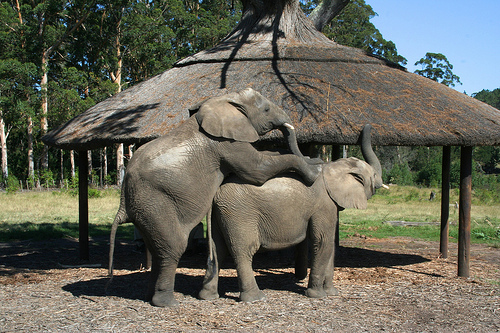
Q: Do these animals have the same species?
A: Yes, all the animals are elephants.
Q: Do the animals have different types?
A: No, all the animals are elephants.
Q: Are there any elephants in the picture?
A: Yes, there is an elephant.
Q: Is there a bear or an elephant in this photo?
A: Yes, there is an elephant.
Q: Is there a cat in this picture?
A: No, there are no cats.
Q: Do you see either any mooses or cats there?
A: No, there are no cats or mooses.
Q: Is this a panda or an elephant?
A: This is an elephant.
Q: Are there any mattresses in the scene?
A: No, there are no mattresses.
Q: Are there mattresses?
A: No, there are no mattresses.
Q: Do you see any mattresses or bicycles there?
A: No, there are no mattresses or bicycles.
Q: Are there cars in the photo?
A: No, there are no cars.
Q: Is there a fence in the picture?
A: Yes, there is a fence.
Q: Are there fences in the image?
A: Yes, there is a fence.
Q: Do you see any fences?
A: Yes, there is a fence.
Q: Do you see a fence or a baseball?
A: Yes, there is a fence.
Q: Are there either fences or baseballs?
A: Yes, there is a fence.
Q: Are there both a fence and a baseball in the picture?
A: No, there is a fence but no baseballs.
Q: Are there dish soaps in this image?
A: No, there are no dish soaps.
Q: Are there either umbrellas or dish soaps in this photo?
A: No, there are no dish soaps or umbrellas.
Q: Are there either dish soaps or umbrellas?
A: No, there are no dish soaps or umbrellas.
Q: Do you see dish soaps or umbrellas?
A: No, there are no dish soaps or umbrellas.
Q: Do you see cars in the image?
A: No, there are no cars.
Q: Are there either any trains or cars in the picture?
A: No, there are no cars or trains.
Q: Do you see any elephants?
A: Yes, there is an elephant.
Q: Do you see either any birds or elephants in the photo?
A: Yes, there is an elephant.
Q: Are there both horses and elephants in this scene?
A: No, there is an elephant but no horses.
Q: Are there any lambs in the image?
A: No, there are no lambs.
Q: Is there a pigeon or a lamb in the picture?
A: No, there are no lambs or pigeons.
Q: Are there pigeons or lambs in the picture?
A: No, there are no lambs or pigeons.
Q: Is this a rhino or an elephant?
A: This is an elephant.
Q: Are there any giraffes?
A: No, there are no giraffes.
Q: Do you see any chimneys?
A: No, there are no chimneys.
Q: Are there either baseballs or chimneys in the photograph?
A: No, there are no chimneys or baseballs.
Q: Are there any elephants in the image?
A: Yes, there are elephants.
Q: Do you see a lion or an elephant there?
A: Yes, there are elephants.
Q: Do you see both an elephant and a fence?
A: Yes, there are both an elephant and a fence.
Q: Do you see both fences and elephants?
A: Yes, there are both elephants and a fence.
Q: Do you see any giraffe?
A: No, there are no giraffes.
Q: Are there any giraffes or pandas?
A: No, there are no giraffes or pandas.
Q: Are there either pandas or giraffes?
A: No, there are no giraffes or pandas.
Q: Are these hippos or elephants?
A: These are elephants.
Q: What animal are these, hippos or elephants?
A: These are elephants.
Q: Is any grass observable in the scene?
A: Yes, there is grass.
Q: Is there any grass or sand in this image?
A: Yes, there is grass.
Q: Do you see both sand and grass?
A: No, there is grass but no sand.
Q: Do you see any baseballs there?
A: No, there are no baseballs.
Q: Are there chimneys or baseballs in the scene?
A: No, there are no baseballs or chimneys.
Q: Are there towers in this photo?
A: No, there are no towers.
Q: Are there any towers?
A: No, there are no towers.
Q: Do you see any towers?
A: No, there are no towers.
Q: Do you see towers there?
A: No, there are no towers.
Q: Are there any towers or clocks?
A: No, there are no towers or clocks.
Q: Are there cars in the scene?
A: No, there are no cars.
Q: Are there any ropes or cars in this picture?
A: No, there are no cars or ropes.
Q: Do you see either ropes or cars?
A: No, there are no cars or ropes.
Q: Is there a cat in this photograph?
A: No, there are no cats.